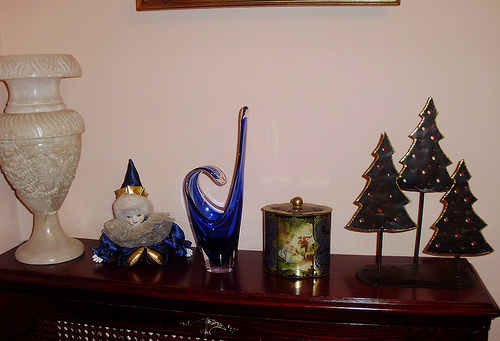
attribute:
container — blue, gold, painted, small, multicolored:
[261, 195, 331, 279]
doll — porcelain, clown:
[92, 158, 194, 267]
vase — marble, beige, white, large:
[0, 53, 85, 265]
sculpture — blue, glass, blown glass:
[183, 106, 250, 273]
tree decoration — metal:
[344, 96, 493, 287]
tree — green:
[422, 160, 495, 260]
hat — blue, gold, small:
[115, 158, 149, 197]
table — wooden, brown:
[2, 237, 497, 316]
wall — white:
[3, 5, 498, 257]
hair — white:
[113, 194, 153, 215]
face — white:
[125, 212, 145, 226]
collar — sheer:
[100, 212, 173, 246]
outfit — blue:
[95, 219, 191, 265]